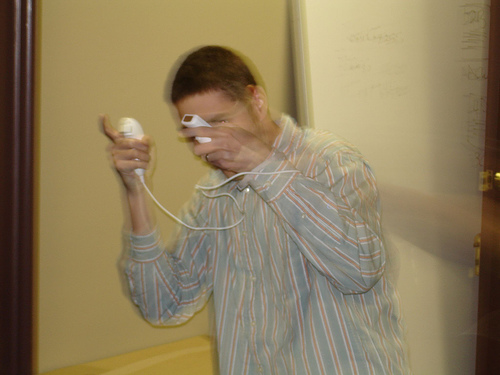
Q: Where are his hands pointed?
A: Forward.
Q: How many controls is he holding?
A: 2.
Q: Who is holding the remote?
A: The guy.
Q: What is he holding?
A: Wii remote.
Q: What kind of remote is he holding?
A: Video game remote.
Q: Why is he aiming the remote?
A: He is playing a virtual video game.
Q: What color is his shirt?
A: Blue stripes.